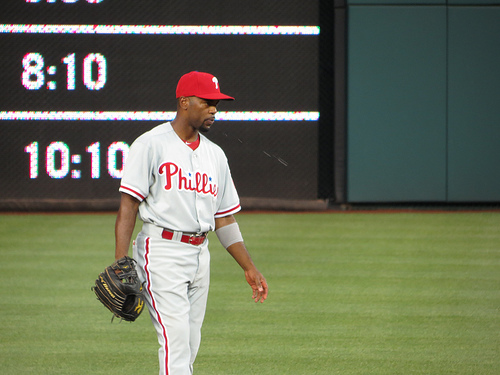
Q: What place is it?
A: It is a field.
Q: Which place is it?
A: It is a field.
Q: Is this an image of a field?
A: Yes, it is showing a field.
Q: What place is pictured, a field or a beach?
A: It is a field.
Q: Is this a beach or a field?
A: It is a field.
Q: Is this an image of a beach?
A: No, the picture is showing a field.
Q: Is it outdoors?
A: Yes, it is outdoors.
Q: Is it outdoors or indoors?
A: It is outdoors.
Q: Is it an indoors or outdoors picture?
A: It is outdoors.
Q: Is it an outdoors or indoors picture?
A: It is outdoors.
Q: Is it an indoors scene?
A: No, it is outdoors.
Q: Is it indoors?
A: No, it is outdoors.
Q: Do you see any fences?
A: No, there are no fences.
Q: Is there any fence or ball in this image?
A: No, there are no fences or balls.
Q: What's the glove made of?
A: The glove is made of leather.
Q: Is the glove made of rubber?
A: No, the glove is made of leather.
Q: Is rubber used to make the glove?
A: No, the glove is made of leather.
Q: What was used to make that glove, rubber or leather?
A: The glove is made of leather.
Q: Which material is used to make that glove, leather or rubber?
A: The glove is made of leather.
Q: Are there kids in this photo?
A: No, there are no kids.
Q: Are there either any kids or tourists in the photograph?
A: No, there are no kids or tourists.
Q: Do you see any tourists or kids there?
A: No, there are no kids or tourists.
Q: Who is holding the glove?
A: The man is holding the glove.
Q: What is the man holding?
A: The man is holding the glove.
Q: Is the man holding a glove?
A: Yes, the man is holding a glove.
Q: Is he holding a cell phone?
A: No, the man is holding a glove.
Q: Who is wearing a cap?
A: The man is wearing a cap.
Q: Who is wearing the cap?
A: The man is wearing a cap.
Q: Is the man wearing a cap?
A: Yes, the man is wearing a cap.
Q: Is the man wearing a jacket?
A: No, the man is wearing a cap.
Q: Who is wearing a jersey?
A: The man is wearing a jersey.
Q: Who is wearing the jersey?
A: The man is wearing a jersey.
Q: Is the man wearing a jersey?
A: Yes, the man is wearing a jersey.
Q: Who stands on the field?
A: The man stands on the field.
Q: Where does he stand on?
A: The man stands on the field.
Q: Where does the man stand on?
A: The man stands on the field.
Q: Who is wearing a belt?
A: The man is wearing a belt.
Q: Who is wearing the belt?
A: The man is wearing a belt.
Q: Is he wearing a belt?
A: Yes, the man is wearing a belt.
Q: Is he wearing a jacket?
A: No, the man is wearing a belt.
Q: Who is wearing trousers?
A: The man is wearing trousers.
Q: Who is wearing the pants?
A: The man is wearing trousers.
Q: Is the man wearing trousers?
A: Yes, the man is wearing trousers.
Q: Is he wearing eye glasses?
A: No, the man is wearing trousers.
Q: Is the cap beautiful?
A: Yes, the cap is beautiful.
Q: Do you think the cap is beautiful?
A: Yes, the cap is beautiful.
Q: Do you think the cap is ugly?
A: No, the cap is beautiful.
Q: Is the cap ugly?
A: No, the cap is beautiful.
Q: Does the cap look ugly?
A: No, the cap is beautiful.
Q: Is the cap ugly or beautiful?
A: The cap is beautiful.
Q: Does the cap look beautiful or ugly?
A: The cap is beautiful.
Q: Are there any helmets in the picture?
A: No, there are no helmets.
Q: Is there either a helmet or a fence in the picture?
A: No, there are no helmets or fences.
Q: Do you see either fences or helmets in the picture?
A: No, there are no helmets or fences.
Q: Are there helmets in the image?
A: No, there are no helmets.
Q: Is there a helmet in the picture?
A: No, there are no helmets.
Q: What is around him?
A: The belt is around the man.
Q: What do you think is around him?
A: The belt is around the man.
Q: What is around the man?
A: The belt is around the man.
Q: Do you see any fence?
A: No, there are no fences.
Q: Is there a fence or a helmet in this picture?
A: No, there are no fences or helmets.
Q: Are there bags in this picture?
A: No, there are no bags.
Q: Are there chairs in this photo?
A: No, there are no chairs.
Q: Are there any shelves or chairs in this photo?
A: No, there are no chairs or shelves.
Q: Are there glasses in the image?
A: No, there are no glasses.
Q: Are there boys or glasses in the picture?
A: No, there are no glasses or boys.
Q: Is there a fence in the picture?
A: No, there are no fences.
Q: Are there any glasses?
A: No, there are no glasses.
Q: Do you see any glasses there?
A: No, there are no glasses.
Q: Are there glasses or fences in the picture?
A: No, there are no glasses or fences.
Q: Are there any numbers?
A: Yes, there are numbers.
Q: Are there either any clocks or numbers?
A: Yes, there are numbers.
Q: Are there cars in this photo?
A: No, there are no cars.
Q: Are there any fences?
A: No, there are no fences.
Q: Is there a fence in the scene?
A: No, there are no fences.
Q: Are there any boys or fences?
A: No, there are no fences or boys.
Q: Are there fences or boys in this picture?
A: No, there are no fences or boys.